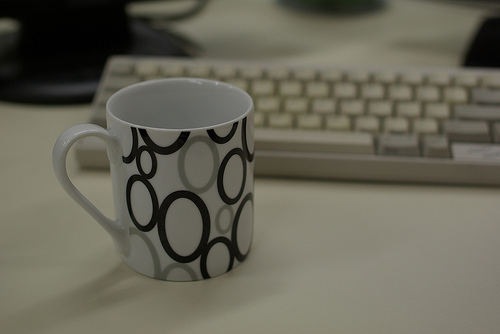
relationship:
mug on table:
[47, 68, 264, 287] [0, 0, 496, 332]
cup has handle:
[55, 66, 267, 291] [52, 122, 129, 242]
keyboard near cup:
[75, 55, 498, 189] [45, 81, 273, 287]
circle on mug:
[178, 135, 218, 192] [50, 76, 255, 282]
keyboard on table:
[245, 57, 499, 164] [0, 0, 496, 332]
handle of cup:
[43, 140, 78, 183] [99, 86, 259, 281]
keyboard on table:
[278, 29, 476, 180] [0, 0, 496, 332]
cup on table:
[44, 73, 259, 284] [0, 0, 496, 332]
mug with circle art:
[50, 76, 255, 282] [217, 144, 247, 209]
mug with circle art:
[50, 76, 255, 282] [213, 202, 235, 234]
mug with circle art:
[50, 76, 255, 282] [125, 171, 160, 232]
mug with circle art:
[50, 76, 255, 282] [199, 233, 237, 280]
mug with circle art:
[50, 76, 255, 282] [135, 128, 190, 153]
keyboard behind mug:
[75, 55, 498, 189] [50, 76, 255, 282]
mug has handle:
[50, 76, 255, 282] [53, 120, 116, 238]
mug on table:
[50, 76, 255, 282] [0, 0, 496, 332]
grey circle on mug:
[175, 134, 221, 190] [50, 76, 255, 282]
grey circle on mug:
[215, 203, 235, 233] [50, 76, 255, 282]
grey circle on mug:
[159, 262, 197, 282] [50, 76, 255, 282]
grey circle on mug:
[126, 225, 161, 279] [50, 76, 255, 282]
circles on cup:
[132, 139, 251, 265] [44, 73, 259, 284]